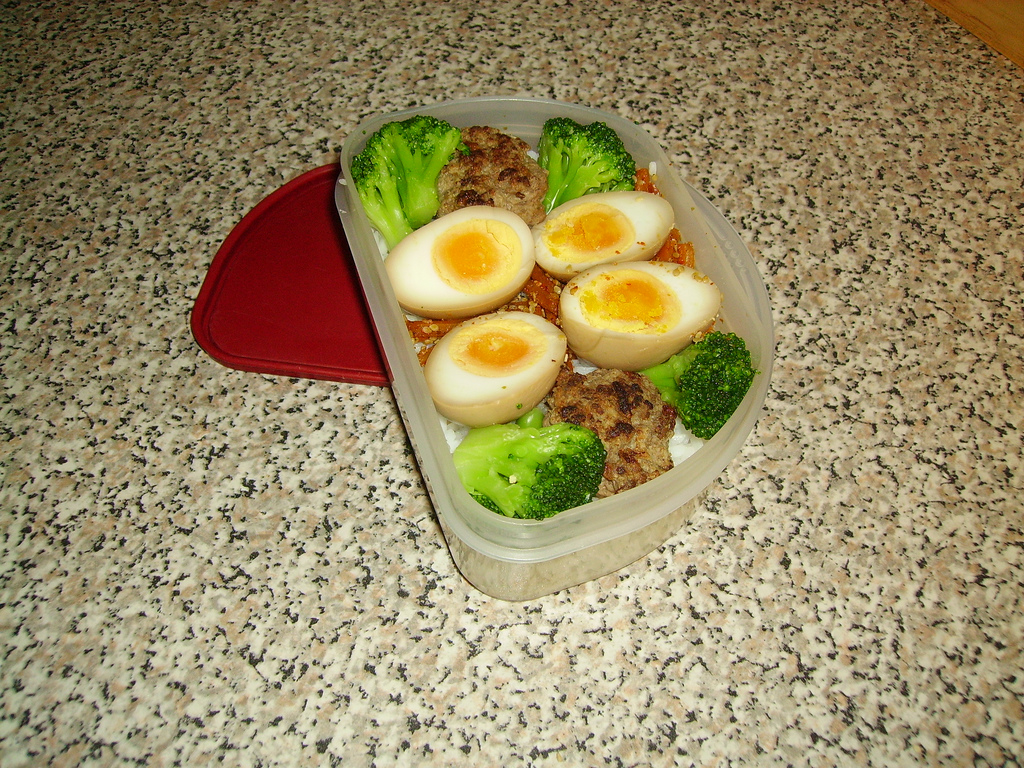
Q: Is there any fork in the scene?
A: No, there are no forks.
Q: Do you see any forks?
A: No, there are no forks.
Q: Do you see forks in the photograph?
A: No, there are no forks.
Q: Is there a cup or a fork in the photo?
A: No, there are no forks or cups.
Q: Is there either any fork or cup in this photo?
A: No, there are no forks or cups.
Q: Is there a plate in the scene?
A: No, there are no plates.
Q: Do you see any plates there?
A: No, there are no plates.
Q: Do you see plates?
A: No, there are no plates.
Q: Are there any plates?
A: No, there are no plates.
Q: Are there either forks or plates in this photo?
A: No, there are no plates or forks.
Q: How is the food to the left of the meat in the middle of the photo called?
A: The food is an egg.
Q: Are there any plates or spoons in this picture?
A: No, there are no plates or spoons.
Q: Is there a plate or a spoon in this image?
A: No, there are no plates or spoons.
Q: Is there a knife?
A: No, there are no knives.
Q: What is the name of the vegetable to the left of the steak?
A: The vegetable is broccoli.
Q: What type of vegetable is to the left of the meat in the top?
A: The vegetable is broccoli.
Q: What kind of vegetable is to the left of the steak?
A: The vegetable is broccoli.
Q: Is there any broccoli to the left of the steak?
A: Yes, there is broccoli to the left of the steak.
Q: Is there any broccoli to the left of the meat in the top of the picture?
A: Yes, there is broccoli to the left of the steak.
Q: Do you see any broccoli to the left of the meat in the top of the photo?
A: Yes, there is broccoli to the left of the steak.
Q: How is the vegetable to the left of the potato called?
A: The vegetable is broccoli.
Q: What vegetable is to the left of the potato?
A: The vegetable is broccoli.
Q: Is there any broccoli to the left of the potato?
A: Yes, there is broccoli to the left of the potato.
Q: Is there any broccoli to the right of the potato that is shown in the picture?
A: No, the broccoli is to the left of the potato.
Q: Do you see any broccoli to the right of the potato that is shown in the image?
A: No, the broccoli is to the left of the potato.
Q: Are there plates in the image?
A: No, there are no plates.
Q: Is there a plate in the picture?
A: No, there are no plates.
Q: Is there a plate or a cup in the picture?
A: No, there are no plates or cups.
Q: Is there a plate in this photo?
A: No, there are no plates.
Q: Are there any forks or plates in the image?
A: No, there are no plates or forks.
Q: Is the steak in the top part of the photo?
A: Yes, the steak is in the top of the image.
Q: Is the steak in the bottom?
A: No, the steak is in the top of the image.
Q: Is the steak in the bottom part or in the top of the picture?
A: The steak is in the top of the image.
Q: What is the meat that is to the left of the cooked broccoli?
A: The meat is a steak.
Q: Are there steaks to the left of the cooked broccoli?
A: Yes, there is a steak to the left of the broccoli.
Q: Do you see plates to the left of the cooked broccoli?
A: No, there is a steak to the left of the broccoli.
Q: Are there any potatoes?
A: Yes, there is a potato.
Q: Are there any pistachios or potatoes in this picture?
A: Yes, there is a potato.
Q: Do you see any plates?
A: No, there are no plates.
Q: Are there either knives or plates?
A: No, there are no plates or knives.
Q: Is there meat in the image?
A: Yes, there is meat.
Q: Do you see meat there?
A: Yes, there is meat.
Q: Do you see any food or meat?
A: Yes, there is meat.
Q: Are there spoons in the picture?
A: No, there are no spoons.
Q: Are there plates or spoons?
A: No, there are no spoons or plates.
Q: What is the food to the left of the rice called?
A: The food is meat.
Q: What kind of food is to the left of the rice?
A: The food is meat.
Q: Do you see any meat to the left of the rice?
A: Yes, there is meat to the left of the rice.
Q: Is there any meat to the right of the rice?
A: No, the meat is to the left of the rice.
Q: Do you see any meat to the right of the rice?
A: No, the meat is to the left of the rice.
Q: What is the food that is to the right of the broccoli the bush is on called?
A: The food is meat.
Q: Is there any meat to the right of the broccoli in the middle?
A: Yes, there is meat to the right of the broccoli.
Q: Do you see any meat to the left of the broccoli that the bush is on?
A: No, the meat is to the right of the broccoli.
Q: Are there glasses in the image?
A: No, there are no glasses.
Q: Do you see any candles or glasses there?
A: No, there are no glasses or candles.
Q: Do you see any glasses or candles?
A: No, there are no glasses or candles.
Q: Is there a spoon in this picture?
A: No, there are no spoons.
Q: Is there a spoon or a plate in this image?
A: No, there are no spoons or plates.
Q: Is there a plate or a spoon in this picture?
A: No, there are no spoons or plates.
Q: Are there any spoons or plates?
A: No, there are no spoons or plates.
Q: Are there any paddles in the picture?
A: No, there are no paddles.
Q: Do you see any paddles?
A: No, there are no paddles.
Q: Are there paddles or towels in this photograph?
A: No, there are no paddles or towels.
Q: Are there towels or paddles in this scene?
A: No, there are no paddles or towels.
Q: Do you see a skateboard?
A: No, there are no skateboards.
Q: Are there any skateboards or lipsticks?
A: No, there are no skateboards or lipsticks.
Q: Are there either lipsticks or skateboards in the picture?
A: No, there are no skateboards or lipsticks.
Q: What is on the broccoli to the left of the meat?
A: The bush is on the broccoli.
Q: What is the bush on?
A: The bush is on the broccoli.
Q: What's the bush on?
A: The bush is on the broccoli.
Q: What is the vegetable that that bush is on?
A: The vegetable is broccoli.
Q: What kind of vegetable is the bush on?
A: The bush is on the broccoli.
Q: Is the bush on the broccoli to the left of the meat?
A: Yes, the bush is on the broccoli.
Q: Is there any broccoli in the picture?
A: Yes, there is broccoli.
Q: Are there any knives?
A: No, there are no knives.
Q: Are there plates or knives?
A: No, there are no knives or plates.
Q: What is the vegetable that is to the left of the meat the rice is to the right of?
A: The vegetable is broccoli.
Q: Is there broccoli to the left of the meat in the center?
A: Yes, there is broccoli to the left of the meat.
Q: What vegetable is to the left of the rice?
A: The vegetable is broccoli.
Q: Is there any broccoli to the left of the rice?
A: Yes, there is broccoli to the left of the rice.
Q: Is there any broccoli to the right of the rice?
A: No, the broccoli is to the left of the rice.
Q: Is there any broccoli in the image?
A: Yes, there is broccoli.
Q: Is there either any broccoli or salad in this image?
A: Yes, there is broccoli.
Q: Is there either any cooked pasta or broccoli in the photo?
A: Yes, there is cooked broccoli.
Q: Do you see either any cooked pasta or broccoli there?
A: Yes, there is cooked broccoli.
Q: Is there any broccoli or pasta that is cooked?
A: Yes, the broccoli is cooked.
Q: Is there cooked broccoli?
A: Yes, there is cooked broccoli.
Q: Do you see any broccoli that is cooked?
A: Yes, there is broccoli that is cooked.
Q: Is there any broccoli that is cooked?
A: Yes, there is broccoli that is cooked.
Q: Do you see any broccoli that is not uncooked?
A: Yes, there is cooked broccoli.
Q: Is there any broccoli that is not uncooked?
A: Yes, there is cooked broccoli.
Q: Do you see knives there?
A: No, there are no knives.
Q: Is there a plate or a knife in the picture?
A: No, there are no knives or plates.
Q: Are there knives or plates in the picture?
A: No, there are no knives or plates.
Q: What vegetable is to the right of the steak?
A: The vegetable is broccoli.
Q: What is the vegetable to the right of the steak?
A: The vegetable is broccoli.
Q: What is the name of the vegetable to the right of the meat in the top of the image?
A: The vegetable is broccoli.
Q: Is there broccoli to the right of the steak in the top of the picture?
A: Yes, there is broccoli to the right of the steak.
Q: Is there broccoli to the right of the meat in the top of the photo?
A: Yes, there is broccoli to the right of the steak.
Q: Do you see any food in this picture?
A: Yes, there is food.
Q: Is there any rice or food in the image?
A: Yes, there is food.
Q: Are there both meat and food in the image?
A: Yes, there are both food and meat.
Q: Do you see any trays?
A: No, there are no trays.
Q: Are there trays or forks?
A: No, there are no trays or forks.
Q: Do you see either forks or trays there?
A: No, there are no trays or forks.